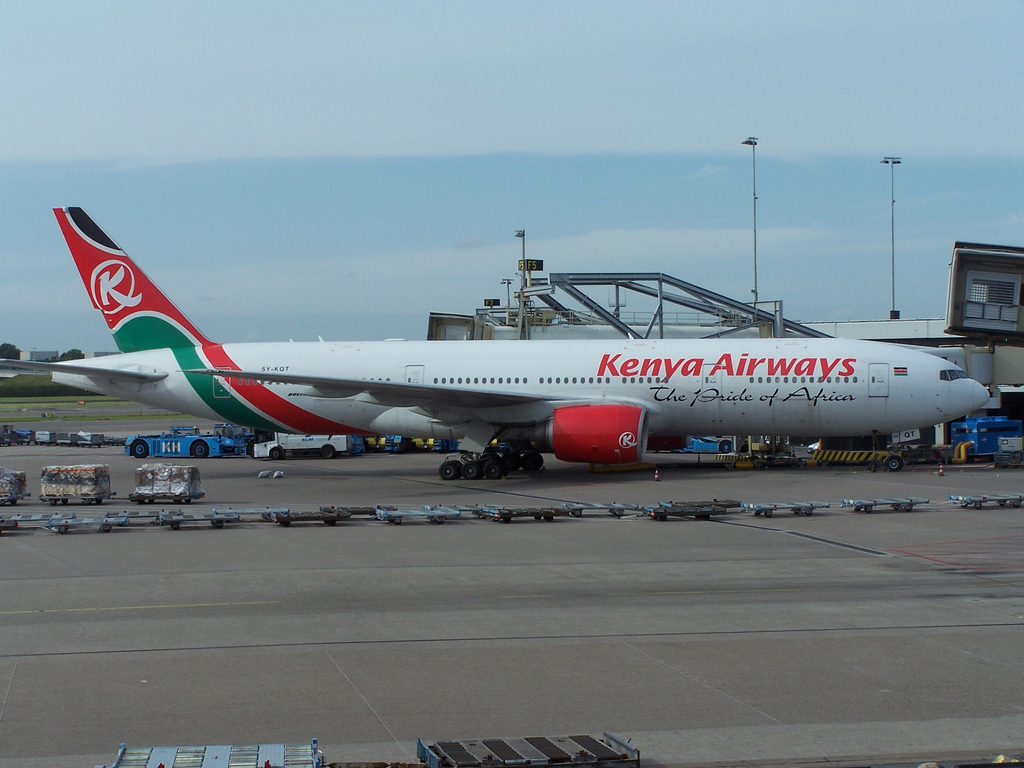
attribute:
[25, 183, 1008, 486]
plane — JET, COMMERCIAL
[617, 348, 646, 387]
letter — red 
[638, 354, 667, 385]
letter — red 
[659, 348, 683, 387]
letter — RED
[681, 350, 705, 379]
letter — RED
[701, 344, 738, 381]
letter — RED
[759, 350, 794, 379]
letter — RED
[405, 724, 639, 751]
trailer — LUGGAGE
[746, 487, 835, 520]
trailer — LUGGAGE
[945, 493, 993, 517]
trailer — LUGGAGE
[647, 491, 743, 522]
trailer — LUGGAGE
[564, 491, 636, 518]
trailer — LUGGAGE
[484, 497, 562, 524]
trailer — LUGGAGE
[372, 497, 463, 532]
trailer — LUGGAGE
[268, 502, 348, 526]
trailer — LUGGAGE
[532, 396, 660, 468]
engine — JET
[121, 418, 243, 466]
tractor — BLUE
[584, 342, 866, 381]
text — RED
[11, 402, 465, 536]
these — LOADING CARTS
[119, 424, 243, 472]
cart — BLUE